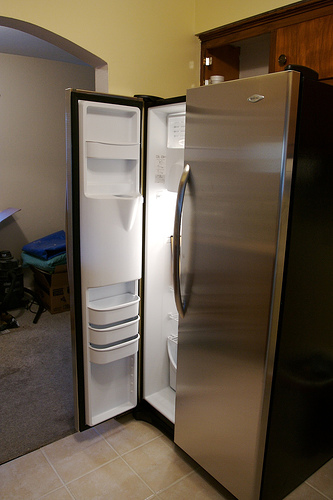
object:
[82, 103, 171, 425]
interior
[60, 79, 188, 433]
freezer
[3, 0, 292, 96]
wall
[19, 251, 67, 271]
blanket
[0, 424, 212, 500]
floor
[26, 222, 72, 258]
blanket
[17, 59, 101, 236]
wall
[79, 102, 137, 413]
plastic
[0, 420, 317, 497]
linoleum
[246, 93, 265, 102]
logo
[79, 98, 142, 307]
shelves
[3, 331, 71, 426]
brown carpet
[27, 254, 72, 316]
box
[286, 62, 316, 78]
black hinge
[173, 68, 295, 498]
silver door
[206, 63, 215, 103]
ground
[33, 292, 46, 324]
hose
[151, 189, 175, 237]
light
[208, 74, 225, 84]
cup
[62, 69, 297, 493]
refrigerator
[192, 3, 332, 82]
cupboard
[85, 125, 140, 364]
rack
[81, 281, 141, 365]
shelves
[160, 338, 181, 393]
drawer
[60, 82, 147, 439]
door